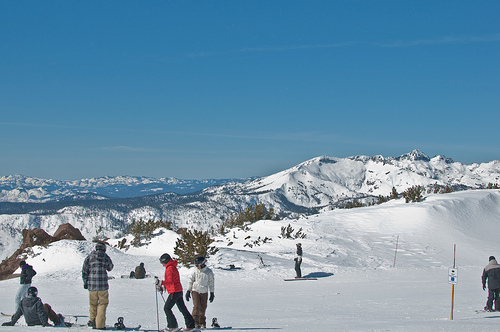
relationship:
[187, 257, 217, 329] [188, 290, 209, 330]
person wearing pants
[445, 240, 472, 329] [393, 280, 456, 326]
markers stuck in snow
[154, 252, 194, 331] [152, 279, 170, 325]
woman holding poles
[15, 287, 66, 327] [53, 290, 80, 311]
person sitting in snow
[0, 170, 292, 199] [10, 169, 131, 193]
mountains in distance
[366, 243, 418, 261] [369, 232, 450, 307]
tracks in snow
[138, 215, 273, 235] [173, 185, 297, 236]
trees growing along mountain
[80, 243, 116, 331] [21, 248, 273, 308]
man on slope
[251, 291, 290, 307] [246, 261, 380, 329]
snow on ground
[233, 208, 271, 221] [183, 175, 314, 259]
shrubs on mountain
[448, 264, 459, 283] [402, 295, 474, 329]
sign in ground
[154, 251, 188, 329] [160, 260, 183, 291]
woman in coat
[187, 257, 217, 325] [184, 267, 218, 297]
person in coat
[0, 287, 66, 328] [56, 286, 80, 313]
person sitting in snow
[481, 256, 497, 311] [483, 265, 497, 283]
man in coat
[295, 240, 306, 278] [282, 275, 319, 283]
person standing on skis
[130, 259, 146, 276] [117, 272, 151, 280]
person sitting with snowboard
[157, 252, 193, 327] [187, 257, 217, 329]
skier next to person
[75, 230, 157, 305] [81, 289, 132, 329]
man with pants